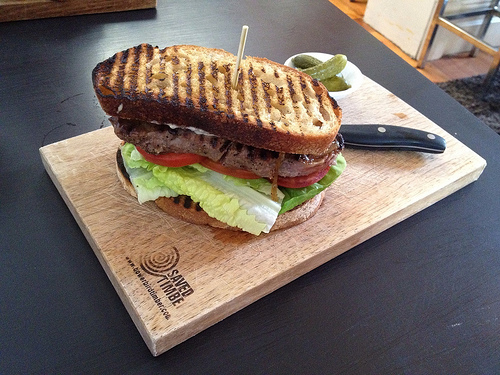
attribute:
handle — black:
[344, 117, 446, 154]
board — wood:
[75, 166, 122, 271]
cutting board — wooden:
[38, 126, 488, 356]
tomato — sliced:
[134, 141, 202, 171]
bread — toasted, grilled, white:
[86, 37, 340, 160]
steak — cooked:
[110, 115, 327, 175]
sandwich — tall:
[88, 43, 348, 236]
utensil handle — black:
[339, 119, 448, 159]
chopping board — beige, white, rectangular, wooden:
[53, 67, 440, 343]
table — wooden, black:
[2, 4, 496, 373]